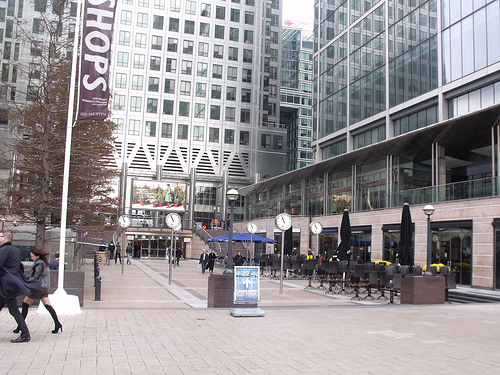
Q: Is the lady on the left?
A: Yes, the lady is on the left of the image.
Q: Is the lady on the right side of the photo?
A: No, the lady is on the left of the image.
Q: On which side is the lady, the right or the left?
A: The lady is on the left of the image.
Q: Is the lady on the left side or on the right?
A: The lady is on the left of the image.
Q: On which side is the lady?
A: The lady is on the left of the image.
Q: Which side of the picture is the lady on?
A: The lady is on the left of the image.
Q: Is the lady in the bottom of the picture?
A: Yes, the lady is in the bottom of the image.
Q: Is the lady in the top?
A: No, the lady is in the bottom of the image.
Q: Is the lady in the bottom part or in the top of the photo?
A: The lady is in the bottom of the image.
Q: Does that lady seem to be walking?
A: Yes, the lady is walking.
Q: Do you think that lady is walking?
A: Yes, the lady is walking.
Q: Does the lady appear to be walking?
A: Yes, the lady is walking.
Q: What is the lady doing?
A: The lady is walking.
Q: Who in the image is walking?
A: The lady is walking.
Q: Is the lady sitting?
A: No, the lady is walking.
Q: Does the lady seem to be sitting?
A: No, the lady is walking.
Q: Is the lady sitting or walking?
A: The lady is walking.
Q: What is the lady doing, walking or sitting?
A: The lady is walking.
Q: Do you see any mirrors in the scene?
A: No, there are no mirrors.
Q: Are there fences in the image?
A: No, there are no fences.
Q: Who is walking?
A: The people are walking.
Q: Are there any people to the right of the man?
A: Yes, there are people to the right of the man.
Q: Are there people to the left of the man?
A: No, the people are to the right of the man.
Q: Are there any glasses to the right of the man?
A: No, there are people to the right of the man.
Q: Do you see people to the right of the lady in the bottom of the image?
A: Yes, there are people to the right of the lady.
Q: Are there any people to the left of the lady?
A: No, the people are to the right of the lady.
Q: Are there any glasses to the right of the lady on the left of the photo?
A: No, there are people to the right of the lady.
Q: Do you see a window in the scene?
A: Yes, there are windows.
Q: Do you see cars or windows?
A: Yes, there are windows.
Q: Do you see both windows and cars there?
A: No, there are windows but no cars.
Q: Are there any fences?
A: No, there are no fences.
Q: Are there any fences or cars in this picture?
A: No, there are no fences or cars.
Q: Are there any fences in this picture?
A: No, there are no fences.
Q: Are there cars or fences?
A: No, there are no fences or cars.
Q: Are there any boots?
A: Yes, there are boots.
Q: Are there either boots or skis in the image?
A: Yes, there are boots.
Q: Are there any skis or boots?
A: Yes, there are boots.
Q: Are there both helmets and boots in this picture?
A: No, there are boots but no helmets.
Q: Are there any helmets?
A: No, there are no helmets.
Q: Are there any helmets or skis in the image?
A: No, there are no helmets or skis.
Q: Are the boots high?
A: Yes, the boots are high.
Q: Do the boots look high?
A: Yes, the boots are high.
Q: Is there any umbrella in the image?
A: Yes, there is an umbrella.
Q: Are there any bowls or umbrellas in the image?
A: Yes, there is an umbrella.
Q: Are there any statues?
A: No, there are no statues.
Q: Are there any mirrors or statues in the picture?
A: No, there are no statues or mirrors.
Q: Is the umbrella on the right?
A: Yes, the umbrella is on the right of the image.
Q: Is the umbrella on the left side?
A: No, the umbrella is on the right of the image.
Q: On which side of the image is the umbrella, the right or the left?
A: The umbrella is on the right of the image.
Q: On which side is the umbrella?
A: The umbrella is on the right of the image.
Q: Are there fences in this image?
A: No, there are no fences.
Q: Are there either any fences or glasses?
A: No, there are no fences or glasses.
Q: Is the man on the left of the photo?
A: Yes, the man is on the left of the image.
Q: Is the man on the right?
A: No, the man is on the left of the image.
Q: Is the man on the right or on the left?
A: The man is on the left of the image.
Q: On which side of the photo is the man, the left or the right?
A: The man is on the left of the image.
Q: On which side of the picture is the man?
A: The man is on the left of the image.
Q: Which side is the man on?
A: The man is on the left of the image.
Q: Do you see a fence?
A: No, there are no fences.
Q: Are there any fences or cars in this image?
A: No, there are no fences or cars.